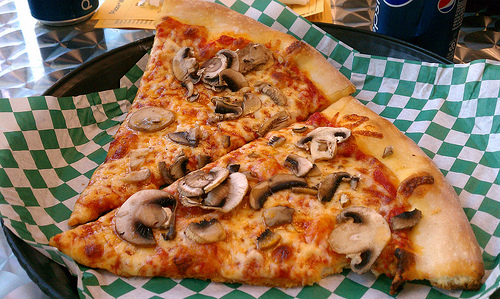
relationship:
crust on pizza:
[317, 93, 486, 292] [49, 1, 484, 296]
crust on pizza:
[326, 99, 483, 289] [42, 91, 491, 296]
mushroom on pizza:
[295, 122, 349, 161] [28, 25, 490, 292]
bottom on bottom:
[34, 7, 104, 27] [24, 0, 102, 28]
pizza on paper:
[49, 1, 484, 296] [3, 20, 498, 297]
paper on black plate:
[3, 20, 498, 297] [0, 21, 500, 299]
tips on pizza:
[48, 208, 111, 269] [49, 1, 484, 296]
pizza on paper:
[45, 94, 484, 296] [3, 20, 498, 297]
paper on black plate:
[3, 20, 498, 297] [3, 18, 455, 297]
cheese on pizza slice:
[228, 230, 243, 247] [46, 101, 481, 284]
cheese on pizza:
[228, 230, 243, 247] [45, 94, 484, 296]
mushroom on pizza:
[111, 187, 179, 247] [49, 1, 484, 296]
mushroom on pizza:
[328, 205, 392, 275] [49, 1, 484, 296]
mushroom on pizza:
[125, 104, 174, 134] [49, 1, 484, 296]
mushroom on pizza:
[295, 125, 351, 162] [49, 1, 484, 296]